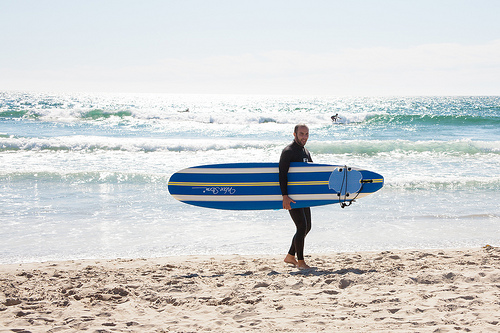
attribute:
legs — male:
[284, 203, 314, 271]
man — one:
[282, 123, 315, 270]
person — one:
[267, 126, 323, 263]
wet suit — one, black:
[287, 204, 309, 231]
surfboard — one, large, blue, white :
[162, 158, 396, 217]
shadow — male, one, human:
[288, 262, 378, 282]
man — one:
[277, 120, 322, 272]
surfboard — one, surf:
[151, 148, 401, 236]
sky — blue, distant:
[63, 7, 400, 64]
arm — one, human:
[280, 145, 295, 210]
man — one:
[278, 124, 311, 268]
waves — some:
[76, 77, 129, 169]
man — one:
[277, 124, 318, 271]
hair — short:
[294, 122, 308, 129]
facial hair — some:
[279, 119, 325, 153]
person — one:
[280, 116, 320, 270]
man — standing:
[269, 124, 341, 254]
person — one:
[165, 100, 386, 271]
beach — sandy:
[14, 75, 497, 320]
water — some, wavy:
[38, 83, 468, 295]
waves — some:
[132, 67, 370, 162]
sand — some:
[0, 243, 500, 331]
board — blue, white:
[171, 149, 388, 213]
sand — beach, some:
[398, 252, 458, 287]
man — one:
[188, 107, 418, 327]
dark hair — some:
[294, 125, 304, 135]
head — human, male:
[268, 119, 329, 149]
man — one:
[247, 114, 399, 296]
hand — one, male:
[277, 195, 297, 212]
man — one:
[272, 120, 317, 272]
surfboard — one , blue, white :
[166, 153, 396, 224]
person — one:
[311, 100, 366, 131]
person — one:
[276, 120, 316, 272]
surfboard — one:
[162, 158, 387, 213]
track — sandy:
[248, 274, 275, 294]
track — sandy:
[315, 285, 346, 300]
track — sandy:
[384, 305, 401, 315]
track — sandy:
[441, 267, 460, 288]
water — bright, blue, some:
[8, 90, 499, 233]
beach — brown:
[0, 248, 484, 331]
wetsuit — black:
[276, 141, 316, 261]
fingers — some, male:
[281, 194, 296, 212]